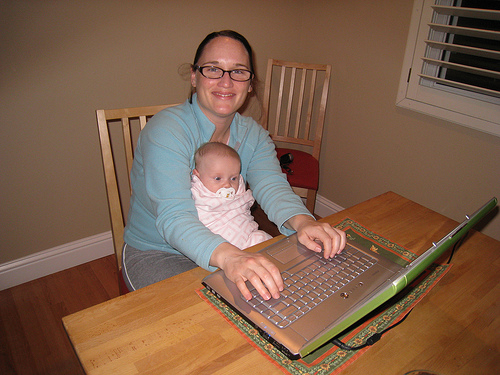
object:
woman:
[111, 22, 344, 298]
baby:
[189, 141, 264, 247]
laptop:
[195, 187, 500, 359]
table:
[60, 185, 500, 374]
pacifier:
[212, 185, 238, 202]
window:
[384, 0, 500, 148]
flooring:
[4, 185, 341, 374]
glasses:
[191, 62, 259, 81]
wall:
[1, 0, 499, 273]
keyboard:
[204, 230, 390, 334]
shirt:
[119, 93, 327, 263]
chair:
[85, 101, 187, 292]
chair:
[245, 55, 339, 225]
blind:
[413, 72, 499, 109]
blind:
[418, 55, 500, 82]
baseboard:
[0, 228, 128, 291]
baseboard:
[309, 189, 350, 224]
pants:
[112, 234, 210, 300]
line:
[118, 238, 141, 302]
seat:
[253, 144, 326, 192]